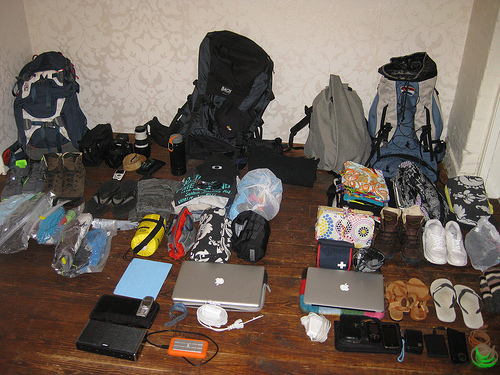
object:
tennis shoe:
[422, 220, 446, 267]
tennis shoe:
[448, 221, 468, 267]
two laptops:
[170, 261, 384, 312]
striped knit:
[300, 275, 385, 320]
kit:
[312, 236, 357, 271]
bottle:
[165, 133, 186, 176]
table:
[0, 133, 500, 375]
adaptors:
[196, 304, 264, 332]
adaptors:
[300, 312, 332, 344]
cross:
[336, 261, 347, 270]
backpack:
[289, 73, 377, 176]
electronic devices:
[332, 312, 402, 354]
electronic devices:
[400, 326, 424, 354]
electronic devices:
[420, 324, 451, 359]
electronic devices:
[446, 329, 469, 364]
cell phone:
[167, 336, 209, 358]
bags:
[0, 192, 53, 254]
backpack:
[365, 51, 448, 183]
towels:
[446, 173, 488, 225]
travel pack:
[130, 213, 167, 257]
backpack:
[167, 30, 276, 171]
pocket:
[182, 90, 222, 137]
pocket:
[246, 87, 275, 121]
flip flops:
[429, 278, 485, 330]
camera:
[110, 132, 127, 165]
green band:
[470, 345, 499, 370]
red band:
[468, 321, 490, 343]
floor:
[4, 268, 74, 368]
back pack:
[12, 51, 91, 161]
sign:
[356, 226, 368, 238]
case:
[313, 237, 356, 270]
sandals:
[385, 275, 431, 321]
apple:
[214, 277, 224, 286]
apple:
[340, 282, 350, 291]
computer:
[171, 260, 268, 312]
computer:
[303, 265, 385, 313]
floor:
[222, 313, 298, 375]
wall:
[22, 3, 473, 145]